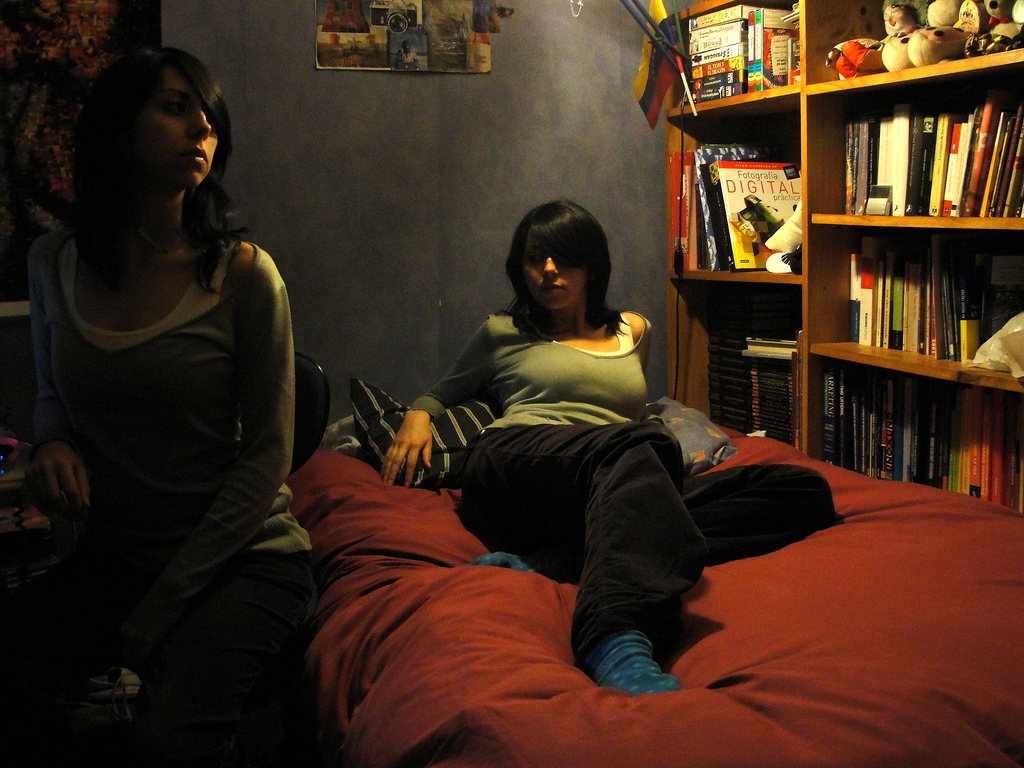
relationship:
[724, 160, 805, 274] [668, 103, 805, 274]
book on shelf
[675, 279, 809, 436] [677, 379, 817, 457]
book on shelf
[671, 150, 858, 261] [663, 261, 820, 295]
book on shelf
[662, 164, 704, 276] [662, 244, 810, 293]
book on shelf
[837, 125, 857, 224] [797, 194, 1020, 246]
book on shelf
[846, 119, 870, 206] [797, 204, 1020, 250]
book on shelf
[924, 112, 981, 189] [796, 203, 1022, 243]
book on shelf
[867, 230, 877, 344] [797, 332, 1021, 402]
book on shelf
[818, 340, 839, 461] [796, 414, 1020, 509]
book on shelf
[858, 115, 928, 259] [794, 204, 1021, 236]
book on shelf